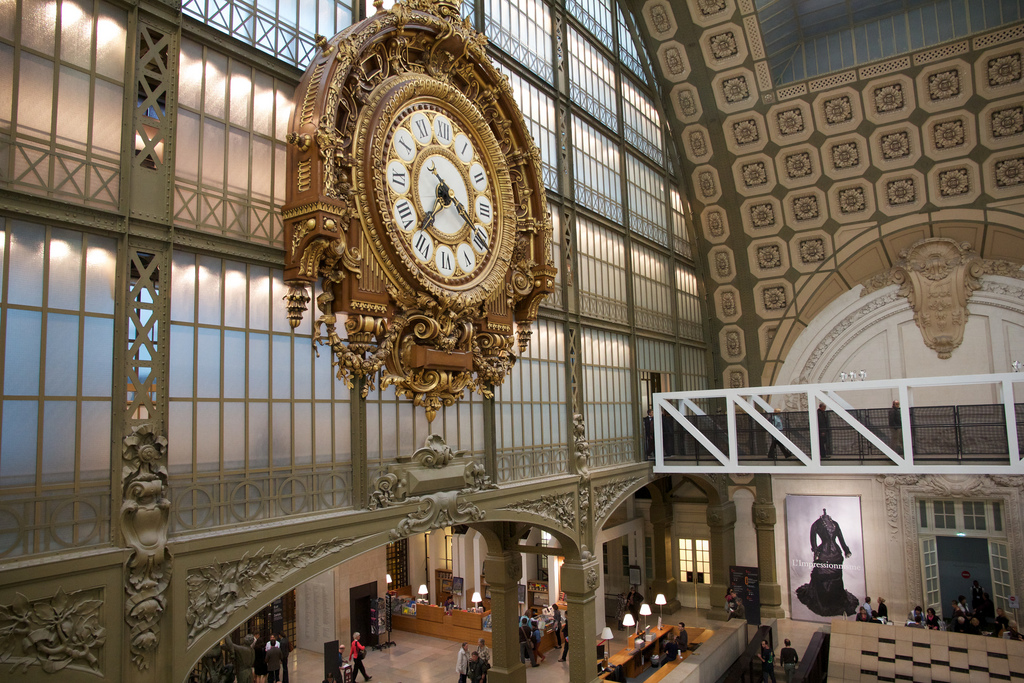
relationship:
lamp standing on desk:
[417, 579, 424, 593] [386, 580, 486, 624]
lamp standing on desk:
[466, 584, 486, 602] [401, 593, 510, 648]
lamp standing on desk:
[600, 625, 614, 658] [594, 619, 681, 676]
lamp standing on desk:
[624, 608, 637, 648] [598, 619, 679, 674]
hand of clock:
[445, 191, 495, 254] [293, 3, 564, 388]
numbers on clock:
[322, 55, 571, 302] [293, 18, 644, 399]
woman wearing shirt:
[296, 582, 417, 678] [337, 633, 392, 679]